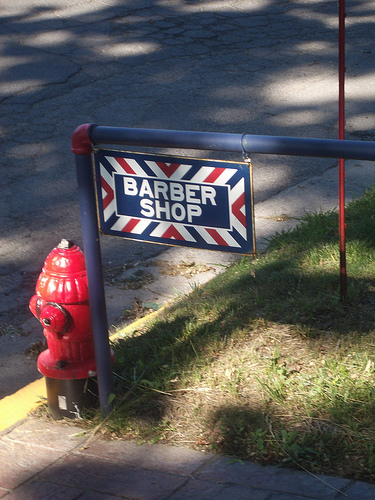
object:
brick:
[70, 427, 220, 477]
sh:
[139, 199, 170, 220]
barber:
[123, 177, 217, 206]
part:
[117, 335, 170, 402]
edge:
[0, 414, 31, 441]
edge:
[34, 411, 375, 487]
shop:
[139, 198, 202, 222]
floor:
[0, 416, 375, 499]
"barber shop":
[124, 177, 218, 223]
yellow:
[0, 378, 46, 432]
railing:
[92, 125, 375, 162]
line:
[227, 226, 247, 248]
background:
[100, 156, 248, 247]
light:
[163, 317, 374, 447]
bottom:
[46, 376, 99, 420]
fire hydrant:
[28, 239, 99, 420]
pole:
[75, 150, 109, 410]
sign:
[93, 148, 256, 255]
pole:
[336, 1, 346, 302]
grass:
[85, 199, 374, 480]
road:
[0, 0, 372, 401]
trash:
[105, 259, 210, 287]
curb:
[0, 308, 165, 431]